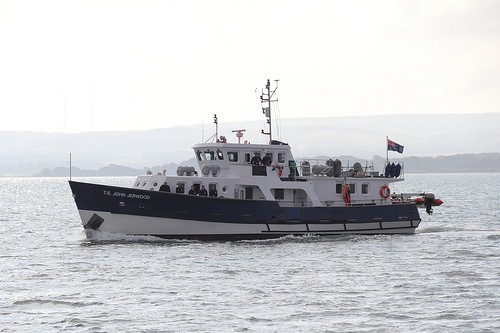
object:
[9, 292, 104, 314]
wave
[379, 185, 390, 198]
device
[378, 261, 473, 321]
waves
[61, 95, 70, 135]
poles outlined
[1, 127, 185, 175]
mountain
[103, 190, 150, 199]
letters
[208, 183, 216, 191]
windows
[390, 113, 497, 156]
mountain slopes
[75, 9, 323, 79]
bright light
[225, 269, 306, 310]
wave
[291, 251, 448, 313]
ocean water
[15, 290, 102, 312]
wave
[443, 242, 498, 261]
wave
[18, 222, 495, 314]
ocean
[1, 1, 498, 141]
sky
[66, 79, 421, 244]
boat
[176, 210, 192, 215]
stripe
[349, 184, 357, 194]
window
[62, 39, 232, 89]
cloud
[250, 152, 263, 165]
person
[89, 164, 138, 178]
mountains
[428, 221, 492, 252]
ripples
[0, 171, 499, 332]
water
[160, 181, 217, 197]
people